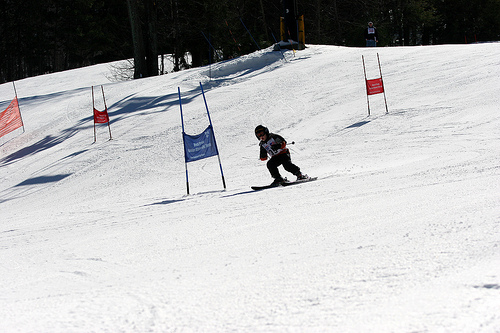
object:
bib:
[260, 137, 283, 157]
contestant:
[255, 125, 309, 185]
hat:
[253, 125, 268, 141]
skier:
[366, 22, 379, 46]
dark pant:
[265, 148, 301, 181]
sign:
[84, 79, 116, 144]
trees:
[0, 0, 499, 82]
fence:
[0, 81, 27, 148]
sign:
[173, 82, 227, 194]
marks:
[421, 111, 468, 188]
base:
[133, 39, 158, 78]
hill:
[0, 24, 496, 330]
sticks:
[285, 140, 294, 146]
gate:
[89, 84, 113, 143]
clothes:
[256, 133, 301, 180]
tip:
[292, 141, 295, 145]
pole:
[276, 140, 294, 150]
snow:
[0, 42, 499, 333]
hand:
[260, 155, 267, 160]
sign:
[357, 53, 392, 115]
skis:
[255, 167, 333, 202]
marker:
[88, 84, 112, 143]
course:
[0, 0, 499, 333]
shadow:
[222, 181, 280, 198]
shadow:
[150, 195, 185, 208]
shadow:
[344, 113, 373, 134]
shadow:
[0, 145, 90, 203]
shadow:
[0, 75, 226, 167]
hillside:
[0, 41, 498, 330]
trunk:
[123, 1, 163, 78]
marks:
[343, 241, 385, 258]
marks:
[61, 248, 123, 288]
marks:
[290, 94, 345, 119]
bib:
[366, 22, 378, 34]